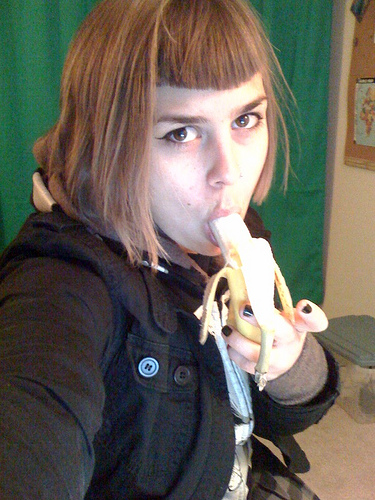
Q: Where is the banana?
A: In her mouth.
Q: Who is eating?
A: The girl.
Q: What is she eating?
A: Banana.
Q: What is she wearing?
A: A shirt.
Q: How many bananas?
A: 1.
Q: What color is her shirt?
A: Black.